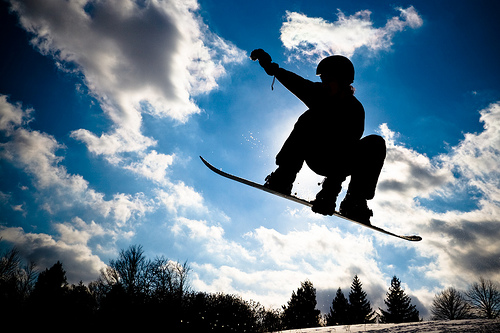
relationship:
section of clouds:
[16, 2, 236, 126] [15, 11, 248, 188]